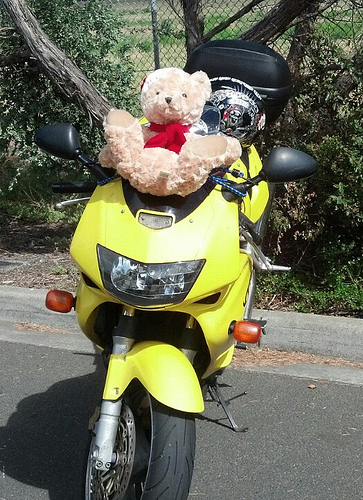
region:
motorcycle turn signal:
[229, 319, 261, 343]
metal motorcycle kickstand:
[204, 377, 248, 434]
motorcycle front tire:
[74, 374, 195, 495]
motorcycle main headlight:
[92, 243, 205, 304]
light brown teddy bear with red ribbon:
[98, 65, 241, 194]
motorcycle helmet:
[199, 77, 268, 140]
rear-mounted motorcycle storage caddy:
[181, 39, 288, 127]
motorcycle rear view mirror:
[222, 146, 318, 202]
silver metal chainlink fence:
[76, 1, 362, 100]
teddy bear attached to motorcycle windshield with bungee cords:
[44, 36, 315, 498]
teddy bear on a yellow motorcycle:
[25, 37, 321, 499]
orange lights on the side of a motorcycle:
[39, 283, 265, 348]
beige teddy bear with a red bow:
[96, 65, 244, 199]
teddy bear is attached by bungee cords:
[85, 59, 253, 215]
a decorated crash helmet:
[198, 70, 269, 156]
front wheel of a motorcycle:
[74, 331, 208, 497]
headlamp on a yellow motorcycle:
[91, 239, 213, 316]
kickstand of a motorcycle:
[204, 368, 253, 438]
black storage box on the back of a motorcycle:
[177, 34, 295, 133]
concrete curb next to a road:
[0, 278, 362, 382]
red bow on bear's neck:
[148, 111, 202, 145]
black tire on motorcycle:
[141, 412, 201, 498]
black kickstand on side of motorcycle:
[218, 366, 266, 457]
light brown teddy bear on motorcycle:
[104, 54, 237, 195]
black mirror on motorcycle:
[266, 134, 315, 181]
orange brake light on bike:
[33, 276, 80, 331]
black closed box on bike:
[194, 32, 289, 95]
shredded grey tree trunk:
[20, 29, 84, 83]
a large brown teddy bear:
[95, 66, 244, 197]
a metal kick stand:
[202, 374, 252, 433]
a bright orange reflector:
[231, 317, 262, 345]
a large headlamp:
[87, 241, 206, 308]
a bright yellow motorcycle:
[22, 102, 330, 499]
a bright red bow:
[143, 121, 191, 154]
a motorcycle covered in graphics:
[200, 74, 276, 150]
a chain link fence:
[94, 0, 356, 35]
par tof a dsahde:
[46, 449, 67, 467]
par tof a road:
[260, 419, 278, 457]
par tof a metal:
[99, 394, 124, 443]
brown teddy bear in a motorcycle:
[108, 95, 204, 170]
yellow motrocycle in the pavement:
[84, 201, 226, 307]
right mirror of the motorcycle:
[276, 146, 314, 185]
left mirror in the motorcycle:
[23, 127, 85, 156]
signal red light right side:
[235, 314, 259, 343]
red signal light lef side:
[45, 293, 75, 314]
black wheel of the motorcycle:
[111, 376, 162, 497]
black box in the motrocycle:
[193, 49, 278, 115]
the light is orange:
[236, 325, 257, 342]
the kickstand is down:
[208, 373, 255, 445]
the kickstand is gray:
[214, 381, 261, 448]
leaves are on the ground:
[241, 344, 354, 414]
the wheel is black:
[107, 382, 192, 495]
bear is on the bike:
[118, 63, 215, 193]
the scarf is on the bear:
[145, 118, 187, 154]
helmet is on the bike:
[199, 72, 256, 147]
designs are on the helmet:
[217, 81, 251, 133]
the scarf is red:
[143, 118, 194, 152]